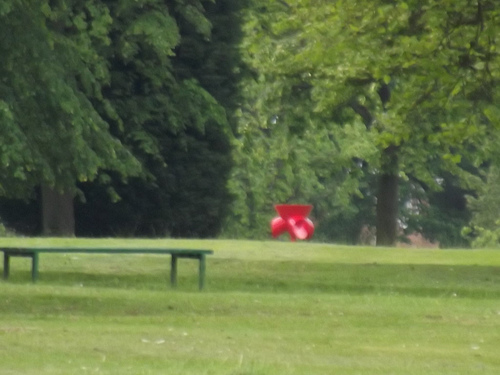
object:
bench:
[1, 247, 210, 290]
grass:
[0, 228, 500, 374]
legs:
[196, 255, 206, 287]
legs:
[2, 251, 12, 283]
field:
[0, 0, 499, 372]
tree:
[0, 2, 223, 238]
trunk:
[39, 159, 77, 238]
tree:
[226, 0, 499, 244]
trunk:
[376, 151, 399, 248]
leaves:
[329, 17, 454, 149]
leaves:
[19, 37, 163, 135]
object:
[271, 204, 314, 242]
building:
[402, 223, 441, 247]